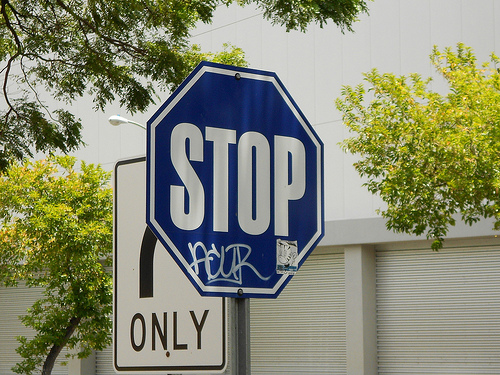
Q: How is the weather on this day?
A: It is clear.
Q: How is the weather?
A: It is clear.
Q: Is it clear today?
A: Yes, it is clear.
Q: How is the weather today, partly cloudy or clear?
A: It is clear.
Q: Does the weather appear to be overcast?
A: No, it is clear.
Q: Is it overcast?
A: No, it is clear.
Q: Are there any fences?
A: No, there are no fences.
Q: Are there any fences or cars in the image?
A: No, there are no fences or cars.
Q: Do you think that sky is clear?
A: Yes, the sky is clear.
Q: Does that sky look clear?
A: Yes, the sky is clear.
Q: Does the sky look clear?
A: Yes, the sky is clear.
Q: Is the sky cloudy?
A: No, the sky is clear.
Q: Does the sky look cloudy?
A: No, the sky is clear.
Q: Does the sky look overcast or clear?
A: The sky is clear.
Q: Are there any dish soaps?
A: No, there are no dish soaps.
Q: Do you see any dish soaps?
A: No, there are no dish soaps.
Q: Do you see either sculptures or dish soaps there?
A: No, there are no dish soaps or sculptures.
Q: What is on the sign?
A: The graffiti is on the sign.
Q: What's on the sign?
A: The graffiti is on the sign.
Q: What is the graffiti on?
A: The graffiti is on the sign.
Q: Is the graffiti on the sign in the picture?
A: Yes, the graffiti is on the sign.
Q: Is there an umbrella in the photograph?
A: No, there are no umbrellas.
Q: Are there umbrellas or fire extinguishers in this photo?
A: No, there are no umbrellas or fire extinguishers.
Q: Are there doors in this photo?
A: Yes, there is a door.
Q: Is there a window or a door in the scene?
A: Yes, there is a door.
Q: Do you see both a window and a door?
A: No, there is a door but no windows.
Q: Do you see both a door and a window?
A: No, there is a door but no windows.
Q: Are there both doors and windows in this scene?
A: No, there is a door but no windows.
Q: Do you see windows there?
A: No, there are no windows.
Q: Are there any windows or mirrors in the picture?
A: No, there are no windows or mirrors.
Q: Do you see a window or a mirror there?
A: No, there are no windows or mirrors.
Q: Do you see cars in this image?
A: No, there are no cars.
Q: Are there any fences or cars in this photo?
A: No, there are no cars or fences.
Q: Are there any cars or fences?
A: No, there are no cars or fences.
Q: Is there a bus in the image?
A: No, there are no buses.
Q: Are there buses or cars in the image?
A: No, there are no buses or cars.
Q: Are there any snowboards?
A: No, there are no snowboards.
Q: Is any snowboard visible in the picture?
A: No, there are no snowboards.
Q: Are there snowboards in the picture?
A: No, there are no snowboards.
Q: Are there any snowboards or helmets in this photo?
A: No, there are no snowboards or helmets.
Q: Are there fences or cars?
A: No, there are no cars or fences.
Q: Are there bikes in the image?
A: No, there are no bikes.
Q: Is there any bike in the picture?
A: No, there are no bikes.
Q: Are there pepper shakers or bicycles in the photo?
A: No, there are no bicycles or pepper shakers.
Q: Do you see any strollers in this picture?
A: No, there are no strollers.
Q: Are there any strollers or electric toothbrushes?
A: No, there are no strollers or electric toothbrushes.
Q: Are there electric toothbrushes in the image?
A: No, there are no electric toothbrushes.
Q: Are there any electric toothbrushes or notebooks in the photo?
A: No, there are no electric toothbrushes or notebooks.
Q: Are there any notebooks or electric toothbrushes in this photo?
A: No, there are no electric toothbrushes or notebooks.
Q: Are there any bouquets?
A: No, there are no bouquets.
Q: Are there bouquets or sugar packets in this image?
A: No, there are no bouquets or sugar packets.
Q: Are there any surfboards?
A: No, there are no surfboards.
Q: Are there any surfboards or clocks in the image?
A: No, there are no surfboards or clocks.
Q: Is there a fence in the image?
A: No, there are no fences.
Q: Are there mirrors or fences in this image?
A: No, there are no fences or mirrors.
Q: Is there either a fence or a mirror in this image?
A: No, there are no fences or mirrors.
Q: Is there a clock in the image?
A: No, there are no clocks.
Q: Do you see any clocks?
A: No, there are no clocks.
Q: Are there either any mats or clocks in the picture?
A: No, there are no clocks or mats.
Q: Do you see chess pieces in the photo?
A: No, there are no chess pieces.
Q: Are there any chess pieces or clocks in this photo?
A: No, there are no chess pieces or clocks.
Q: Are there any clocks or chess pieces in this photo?
A: No, there are no chess pieces or clocks.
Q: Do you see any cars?
A: No, there are no cars.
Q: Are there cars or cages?
A: No, there are no cars or cages.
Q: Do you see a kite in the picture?
A: No, there are no kites.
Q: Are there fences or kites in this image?
A: No, there are no kites or fences.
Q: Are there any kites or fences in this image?
A: No, there are no kites or fences.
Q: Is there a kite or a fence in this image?
A: No, there are no kites or fences.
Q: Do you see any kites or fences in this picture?
A: No, there are no kites or fences.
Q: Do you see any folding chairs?
A: No, there are no folding chairs.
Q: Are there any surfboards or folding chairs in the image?
A: No, there are no folding chairs or surfboards.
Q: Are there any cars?
A: No, there are no cars.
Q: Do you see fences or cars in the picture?
A: No, there are no cars or fences.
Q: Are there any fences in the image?
A: No, there are no fences.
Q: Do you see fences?
A: No, there are no fences.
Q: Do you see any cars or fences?
A: No, there are no fences or cars.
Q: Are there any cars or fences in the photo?
A: No, there are no fences or cars.